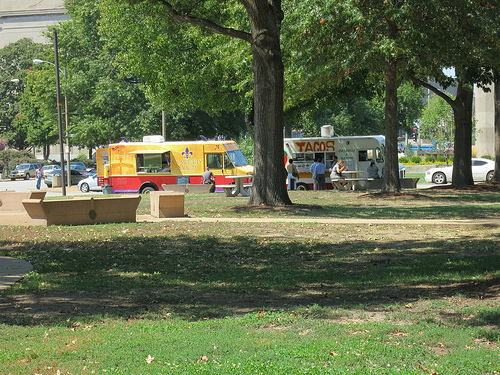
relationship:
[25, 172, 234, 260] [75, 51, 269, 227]
benches in park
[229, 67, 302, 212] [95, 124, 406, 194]
tree in front of trucks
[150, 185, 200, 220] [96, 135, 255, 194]
bench in front of truck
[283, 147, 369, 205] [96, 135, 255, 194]
people in front of truck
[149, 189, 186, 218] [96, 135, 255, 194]
bench near truck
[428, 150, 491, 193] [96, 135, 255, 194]
car near truck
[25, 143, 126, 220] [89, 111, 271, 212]
lot behind truck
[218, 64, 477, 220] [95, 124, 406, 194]
trees behind trucks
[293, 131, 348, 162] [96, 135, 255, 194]
letters on truck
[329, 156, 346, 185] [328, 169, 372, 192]
person eating at table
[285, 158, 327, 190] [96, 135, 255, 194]
people near truck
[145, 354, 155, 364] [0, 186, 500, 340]
leaf on grass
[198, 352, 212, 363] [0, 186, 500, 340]
leaf on grass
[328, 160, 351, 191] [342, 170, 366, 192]
person sitting at table